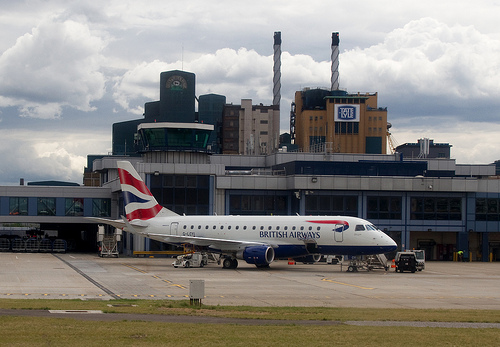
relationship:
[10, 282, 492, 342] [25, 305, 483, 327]
grass in runway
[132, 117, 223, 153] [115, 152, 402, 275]
watchtower in planes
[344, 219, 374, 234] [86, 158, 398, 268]
windshield of airplane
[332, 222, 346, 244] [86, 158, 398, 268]
door of airplane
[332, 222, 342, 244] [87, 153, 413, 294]
door of airplane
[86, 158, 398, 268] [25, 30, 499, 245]
airplane in airport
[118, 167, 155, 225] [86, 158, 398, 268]
design on airplane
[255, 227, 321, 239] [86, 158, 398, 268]
logo on side of airplane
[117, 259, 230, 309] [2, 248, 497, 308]
marking on ground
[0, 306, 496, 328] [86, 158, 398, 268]
sidewalk near airplane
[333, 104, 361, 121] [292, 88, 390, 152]
logo on a building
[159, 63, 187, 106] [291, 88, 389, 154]
logo on a industrial building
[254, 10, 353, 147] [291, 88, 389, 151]
smokestacks from an industrial building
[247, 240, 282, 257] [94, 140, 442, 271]
engine on airplane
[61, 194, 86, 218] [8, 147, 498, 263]
window on building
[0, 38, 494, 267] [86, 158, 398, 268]
airport has airplane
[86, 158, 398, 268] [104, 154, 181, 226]
airplane has tail wing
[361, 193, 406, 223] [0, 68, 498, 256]
window has building